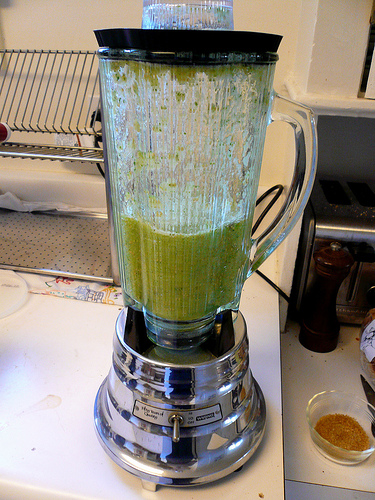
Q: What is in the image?
A: Blender.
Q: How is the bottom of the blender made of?
A: Metal.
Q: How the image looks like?
A: Good.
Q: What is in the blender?
A: Green drink.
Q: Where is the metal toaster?
A: On counter.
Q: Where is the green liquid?
A: In blender.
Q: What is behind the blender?
A: A grate.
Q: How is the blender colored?
A: Colorless.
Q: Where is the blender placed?
A: On white counter.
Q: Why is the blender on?
A: Blending.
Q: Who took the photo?
A: Person blending.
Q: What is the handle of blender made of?
A: Glass.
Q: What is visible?
A: The blender.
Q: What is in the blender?
A: Green stuff.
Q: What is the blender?
A: Silver.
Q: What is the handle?
A: Plastic.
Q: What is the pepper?
A: Crushed.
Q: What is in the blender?
A: Green stuff.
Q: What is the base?
A: Of the blender.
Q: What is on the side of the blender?
A: Green stuff.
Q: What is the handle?
A: Of the blender.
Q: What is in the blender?
A: Green liquid.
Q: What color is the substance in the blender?
A: Green.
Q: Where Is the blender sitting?
A: On the countertop.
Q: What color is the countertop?
A: White.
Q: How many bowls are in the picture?
A: One.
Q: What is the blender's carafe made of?
A: Glass.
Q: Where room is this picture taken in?
A: Kitchen.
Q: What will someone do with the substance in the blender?
A: Drink it.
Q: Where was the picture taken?
A: On the kitchen counter.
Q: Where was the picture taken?
A: The kitchen.